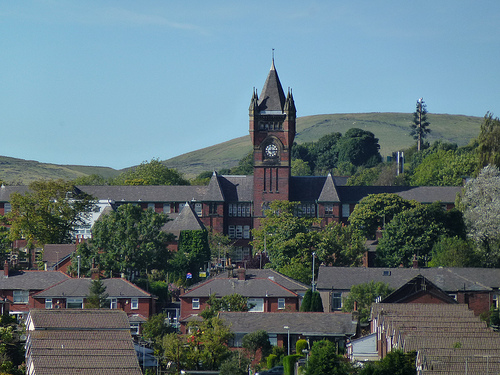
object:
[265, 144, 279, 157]
face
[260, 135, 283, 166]
clock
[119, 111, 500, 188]
hills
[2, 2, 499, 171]
sky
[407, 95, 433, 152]
tree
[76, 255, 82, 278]
telephone pole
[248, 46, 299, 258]
clock tower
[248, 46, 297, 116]
roof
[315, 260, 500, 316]
houses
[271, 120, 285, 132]
windows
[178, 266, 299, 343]
house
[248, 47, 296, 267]
building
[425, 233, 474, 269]
trees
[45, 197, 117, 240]
building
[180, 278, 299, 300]
roof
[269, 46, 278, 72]
spire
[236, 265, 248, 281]
chimney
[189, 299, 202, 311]
window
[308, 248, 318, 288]
telephone pole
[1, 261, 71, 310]
house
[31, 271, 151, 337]
house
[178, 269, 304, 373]
house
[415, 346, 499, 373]
houses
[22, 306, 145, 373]
houses